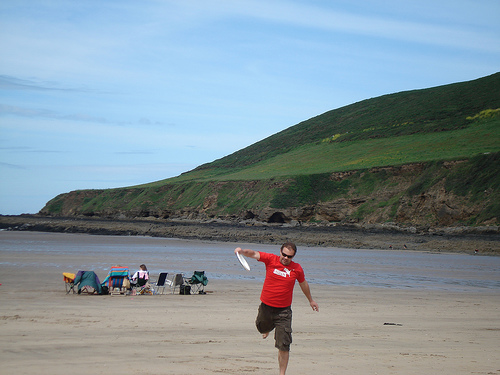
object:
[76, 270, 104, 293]
jacket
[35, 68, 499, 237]
grassy hill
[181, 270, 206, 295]
chairs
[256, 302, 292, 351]
shorts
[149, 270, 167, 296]
chair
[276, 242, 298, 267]
head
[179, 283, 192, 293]
bag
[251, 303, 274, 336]
leg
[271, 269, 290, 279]
white letters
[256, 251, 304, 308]
shirt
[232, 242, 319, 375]
man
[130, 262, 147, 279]
person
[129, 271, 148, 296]
chair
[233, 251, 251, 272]
frisbee